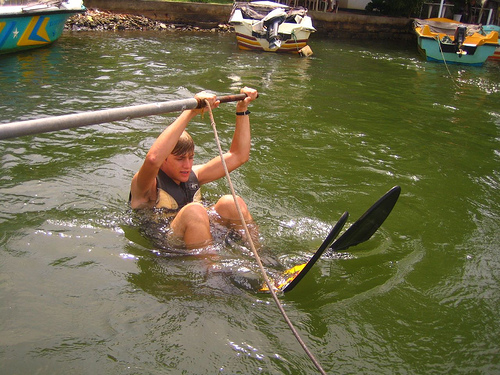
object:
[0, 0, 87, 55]
boat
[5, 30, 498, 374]
water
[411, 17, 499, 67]
boat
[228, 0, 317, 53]
boat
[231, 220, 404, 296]
skis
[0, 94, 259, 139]
ski pole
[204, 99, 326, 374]
rope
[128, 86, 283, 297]
man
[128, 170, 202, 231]
life vest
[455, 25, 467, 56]
motor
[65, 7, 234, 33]
debri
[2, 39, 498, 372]
ripples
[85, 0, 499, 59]
dock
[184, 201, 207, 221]
knees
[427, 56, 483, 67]
stripe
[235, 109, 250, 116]
watch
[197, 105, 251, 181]
left arm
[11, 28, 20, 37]
star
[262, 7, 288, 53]
motor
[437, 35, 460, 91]
rope